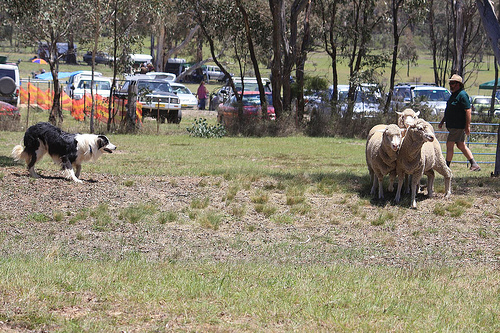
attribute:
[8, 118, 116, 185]
sheep dog — black, white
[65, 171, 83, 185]
paw — white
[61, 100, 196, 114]
fence — red, yellow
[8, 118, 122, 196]
dog — large, black, white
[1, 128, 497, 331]
ground — bare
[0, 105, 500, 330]
grass — light green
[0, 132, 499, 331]
grassy area — large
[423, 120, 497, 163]
fence — blue, metal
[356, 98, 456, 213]
sheep — tan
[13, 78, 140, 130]
fence — orange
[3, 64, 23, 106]
suv — black, white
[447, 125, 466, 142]
shorts — khaki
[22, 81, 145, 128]
fabric — orange, yellow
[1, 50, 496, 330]
field — green, grassy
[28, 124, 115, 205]
dog — black, white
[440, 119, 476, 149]
shorts — khaki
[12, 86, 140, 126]
mesh — orange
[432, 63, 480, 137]
shirt — dark, short sleeve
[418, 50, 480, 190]
hat — tan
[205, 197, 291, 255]
field — grassy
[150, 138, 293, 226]
area — grassy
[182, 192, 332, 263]
area — grassy, green